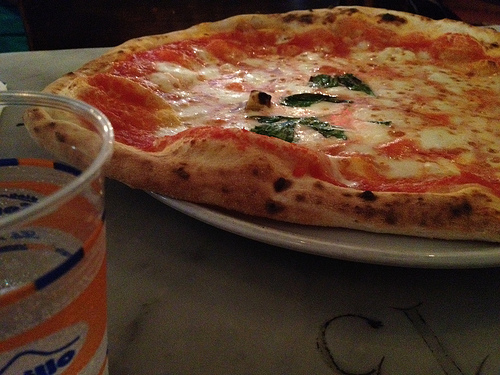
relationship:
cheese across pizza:
[147, 35, 495, 176] [24, 2, 500, 249]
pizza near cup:
[24, 2, 500, 249] [1, 88, 120, 373]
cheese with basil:
[147, 35, 495, 176] [248, 70, 391, 149]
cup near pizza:
[1, 88, 120, 373] [24, 2, 500, 249]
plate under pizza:
[148, 182, 499, 274] [24, 2, 500, 249]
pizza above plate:
[24, 2, 500, 249] [148, 182, 499, 274]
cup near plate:
[1, 88, 120, 373] [148, 182, 499, 274]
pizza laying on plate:
[24, 2, 500, 249] [148, 182, 499, 274]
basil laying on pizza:
[248, 70, 391, 149] [24, 2, 500, 249]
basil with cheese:
[248, 70, 391, 149] [147, 35, 495, 176]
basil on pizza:
[248, 70, 391, 149] [96, 40, 498, 245]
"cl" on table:
[316, 300, 493, 370] [4, 27, 498, 374]